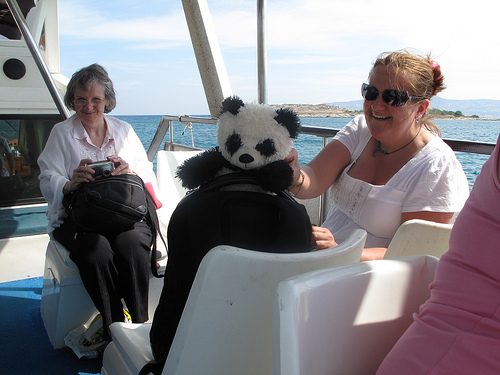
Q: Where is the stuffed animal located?
A: On a boat.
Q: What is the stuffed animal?
A: A panda bear.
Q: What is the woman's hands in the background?
A: A camera.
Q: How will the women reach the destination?
A: By boat.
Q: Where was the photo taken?
A: On a boat.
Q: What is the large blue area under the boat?
A: A body of water.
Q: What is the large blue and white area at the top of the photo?
A: The sky.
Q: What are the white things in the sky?
A: Clouds.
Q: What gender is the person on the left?
A: Female.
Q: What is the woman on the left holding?
A: A camera.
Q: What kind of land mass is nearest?
A: An island.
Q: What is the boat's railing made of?
A: Metal.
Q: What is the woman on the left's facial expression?
A: A smile.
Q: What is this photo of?
A: An ocean.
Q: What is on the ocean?
A: A boat.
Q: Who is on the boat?
A: Two women.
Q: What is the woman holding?
A: A bear.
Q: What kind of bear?
A: A panda.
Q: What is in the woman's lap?
A: A bag.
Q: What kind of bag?
A: A duffle bag.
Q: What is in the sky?
A: Clouds.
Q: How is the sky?
A: Clear.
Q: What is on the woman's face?
A: Sunglasses.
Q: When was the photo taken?
A: Daytime.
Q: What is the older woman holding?
A: A camera.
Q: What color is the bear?
A: Black and white.